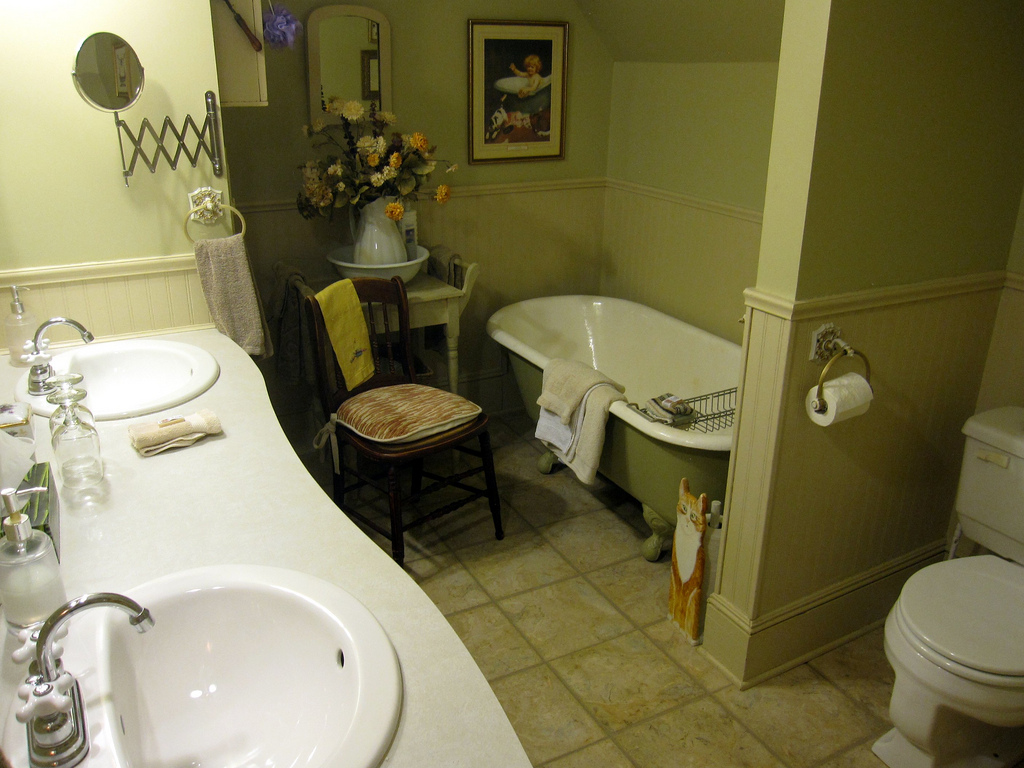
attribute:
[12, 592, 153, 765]
faucet — chrome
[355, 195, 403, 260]
vase — white, ceramic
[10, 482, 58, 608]
soap dispenser — glass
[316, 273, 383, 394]
cloth — yellow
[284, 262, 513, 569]
chair — brown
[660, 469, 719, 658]
cat decor — wooden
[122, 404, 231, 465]
towel — tan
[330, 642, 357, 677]
drain hole — small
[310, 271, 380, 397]
towel — yellow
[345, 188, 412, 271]
vase — white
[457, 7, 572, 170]
art — framed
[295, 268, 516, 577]
chair — brown, wooden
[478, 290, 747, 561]
bath tub — claw foot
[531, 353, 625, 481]
towel — small, tan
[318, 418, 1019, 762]
floor — tiled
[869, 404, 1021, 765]
toilet — white, porcelain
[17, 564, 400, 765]
sink — porcelain, white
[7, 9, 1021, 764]
bathroom — white, porcelain, spacious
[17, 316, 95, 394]
faucet — chrome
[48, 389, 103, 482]
drinking glass — clear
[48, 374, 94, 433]
drinking glass — clear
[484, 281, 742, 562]
bathtub — white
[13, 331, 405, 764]
sinks — white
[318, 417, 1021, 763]
tiles — gray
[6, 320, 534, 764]
counter top — white